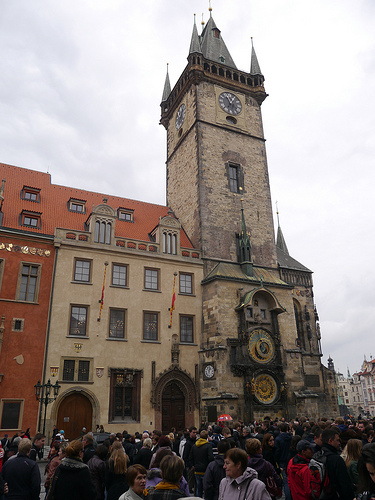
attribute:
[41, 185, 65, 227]
tiles — orange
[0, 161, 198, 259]
roof — tiled, steep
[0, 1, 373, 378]
clouds — white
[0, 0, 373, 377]
sky — blue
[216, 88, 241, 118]
clock face — black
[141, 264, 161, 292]
window — rectangular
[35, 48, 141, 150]
clouds — grey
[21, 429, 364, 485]
crowd — large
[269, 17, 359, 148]
clouds — white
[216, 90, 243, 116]
clock — white, black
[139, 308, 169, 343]
window — rectangular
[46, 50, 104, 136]
clouds — white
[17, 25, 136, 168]
sky — blue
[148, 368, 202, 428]
doorway — arched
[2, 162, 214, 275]
roof — red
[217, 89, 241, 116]
clock — white, round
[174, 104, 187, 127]
clock — round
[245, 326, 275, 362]
clock — round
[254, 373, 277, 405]
clock — round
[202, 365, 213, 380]
clock — round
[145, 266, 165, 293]
windows — small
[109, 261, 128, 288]
windows — small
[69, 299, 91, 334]
windows — small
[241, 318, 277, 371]
clock — astronomical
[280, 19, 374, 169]
clouds — grey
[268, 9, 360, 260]
sky — cloudy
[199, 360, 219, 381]
clock — distant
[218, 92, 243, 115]
clock — black, white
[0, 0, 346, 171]
sky — blue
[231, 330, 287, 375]
clock — astronomical, old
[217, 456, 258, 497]
coat — hooded, tan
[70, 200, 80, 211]
window — small, glass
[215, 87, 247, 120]
clock — astronomical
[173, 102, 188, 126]
clock — astronomical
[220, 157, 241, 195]
window — rectangular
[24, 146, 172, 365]
building — tan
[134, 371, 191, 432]
door — closed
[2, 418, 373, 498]
town square — old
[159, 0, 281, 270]
tower — old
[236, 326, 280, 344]
apostles — hard to discern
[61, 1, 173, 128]
clouds — white